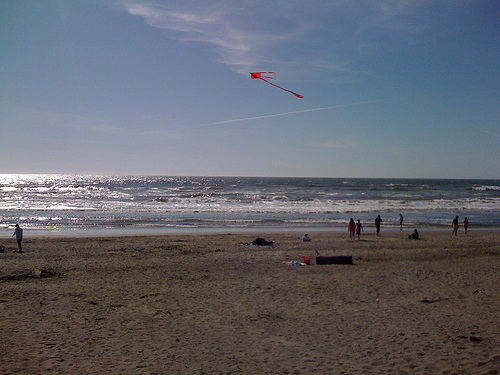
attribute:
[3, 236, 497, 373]
sand — brown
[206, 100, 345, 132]
trail — jet trail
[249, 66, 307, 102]
kite — red, orange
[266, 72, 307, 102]
tail — long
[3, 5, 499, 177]
sky — blue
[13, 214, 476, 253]
person — standing, wearing, sittting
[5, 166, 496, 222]
sea — blue, Breaking waves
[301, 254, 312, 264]
bucket — red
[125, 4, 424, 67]
cloud — high